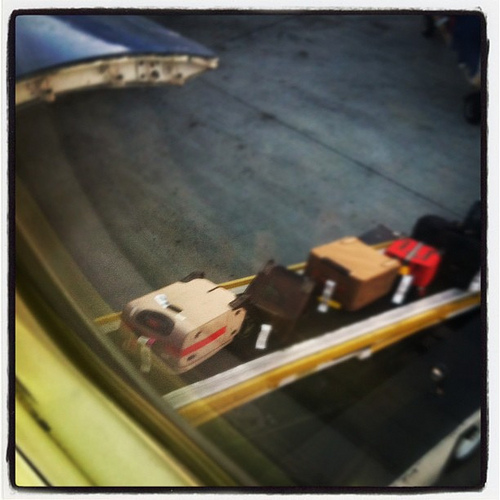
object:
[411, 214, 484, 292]
suitcases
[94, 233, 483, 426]
conveyer belt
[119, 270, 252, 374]
suitcase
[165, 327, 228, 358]
line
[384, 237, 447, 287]
bag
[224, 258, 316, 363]
bag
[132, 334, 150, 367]
tag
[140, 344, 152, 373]
handle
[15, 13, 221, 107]
door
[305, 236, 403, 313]
suitcase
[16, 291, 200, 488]
metal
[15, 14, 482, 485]
airplane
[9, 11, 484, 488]
air field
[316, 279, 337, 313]
tags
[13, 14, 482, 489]
cargo area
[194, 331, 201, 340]
trim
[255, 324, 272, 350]
tag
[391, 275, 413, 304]
tag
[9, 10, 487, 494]
window frame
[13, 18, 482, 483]
pavement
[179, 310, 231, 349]
stripe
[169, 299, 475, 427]
stripe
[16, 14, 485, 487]
window